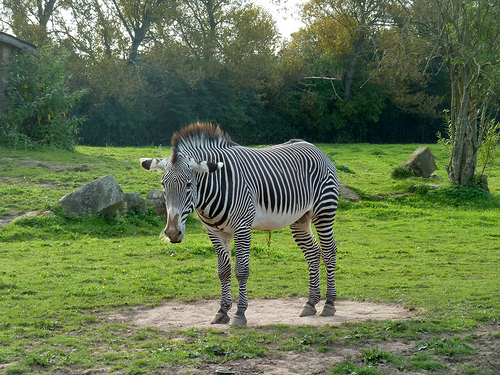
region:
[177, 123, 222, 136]
spiny black hair on the neck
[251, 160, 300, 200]
black stripes on zebra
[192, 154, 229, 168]
a pointy ear on a head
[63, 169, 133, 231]
a large stone lying on the ground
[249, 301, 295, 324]
a patch of dirt in the grass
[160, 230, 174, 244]
white whiskers around a mouth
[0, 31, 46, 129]
an abandoned building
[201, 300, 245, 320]
hooves supporting legs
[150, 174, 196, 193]
black eyes peering at the camera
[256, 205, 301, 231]
a white belly on the zebra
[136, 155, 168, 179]
The zebra's left ear.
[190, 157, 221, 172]
The zebra's right ear.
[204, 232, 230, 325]
The zebra's front left leg.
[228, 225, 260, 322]
The zebra's front right leg.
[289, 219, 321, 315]
The zebra's back left leg.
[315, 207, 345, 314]
The zebra's back right leg.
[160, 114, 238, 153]
The zebra's hair on the back of its neck.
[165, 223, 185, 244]
The zebra's nose and nostrils.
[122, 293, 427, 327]
The circle shaped dirt patch the zebra is standing on.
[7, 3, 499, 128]
The trees in the background.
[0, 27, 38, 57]
The grey roof of a building.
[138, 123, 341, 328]
A black and white zebra.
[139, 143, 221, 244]
A zebra with head lowered.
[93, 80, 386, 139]
Trees with dark green foliage.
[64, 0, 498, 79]
Trees with lighter green foliage.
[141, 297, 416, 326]
A patch of dirt.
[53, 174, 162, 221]
A big rock on the ground.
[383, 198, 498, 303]
The green grass on the ground.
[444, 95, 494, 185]
The grey bark of the tree.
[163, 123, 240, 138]
The zebra's brown mane.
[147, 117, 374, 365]
zebra is black and white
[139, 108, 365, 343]
umbrella is black and white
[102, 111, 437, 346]
zebra standing in circle of dirt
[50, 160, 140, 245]
large and angular grey rock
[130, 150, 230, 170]
ears pointing horizontally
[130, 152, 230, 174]
white tips at end of both ears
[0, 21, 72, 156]
building hidden by bushes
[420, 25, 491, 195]
tree with branches along the trunk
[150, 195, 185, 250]
brown nose on zebra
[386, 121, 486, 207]
angular rock near tree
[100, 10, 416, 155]
tall and short trees behind zebra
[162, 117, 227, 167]
brown fur on tips of mane